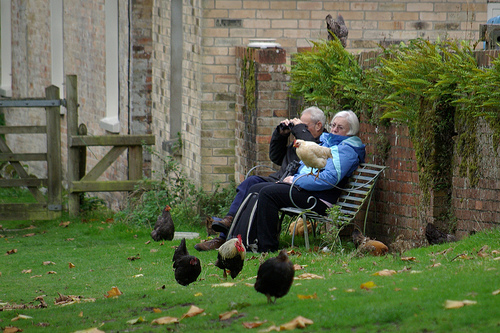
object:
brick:
[418, 11, 447, 22]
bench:
[243, 162, 386, 249]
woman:
[230, 108, 366, 254]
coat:
[292, 131, 365, 192]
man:
[193, 106, 329, 252]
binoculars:
[278, 122, 295, 130]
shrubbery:
[283, 27, 499, 121]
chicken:
[291, 137, 335, 179]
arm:
[291, 144, 359, 191]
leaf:
[489, 288, 500, 295]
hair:
[328, 108, 361, 137]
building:
[0, 0, 492, 222]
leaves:
[408, 66, 418, 73]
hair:
[297, 105, 325, 128]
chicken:
[254, 249, 296, 304]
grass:
[0, 188, 499, 332]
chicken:
[215, 233, 250, 281]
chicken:
[169, 236, 202, 288]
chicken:
[148, 205, 175, 243]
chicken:
[321, 12, 349, 50]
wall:
[203, 2, 492, 209]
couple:
[193, 105, 364, 254]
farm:
[0, 175, 499, 332]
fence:
[0, 81, 65, 222]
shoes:
[193, 233, 225, 252]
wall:
[289, 45, 500, 250]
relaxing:
[194, 104, 387, 255]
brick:
[364, 11, 394, 21]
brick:
[338, 10, 367, 20]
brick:
[282, 10, 311, 20]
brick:
[270, 18, 297, 29]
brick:
[238, 18, 271, 29]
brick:
[198, 28, 230, 39]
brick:
[203, 63, 229, 75]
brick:
[200, 155, 228, 168]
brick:
[405, 2, 433, 12]